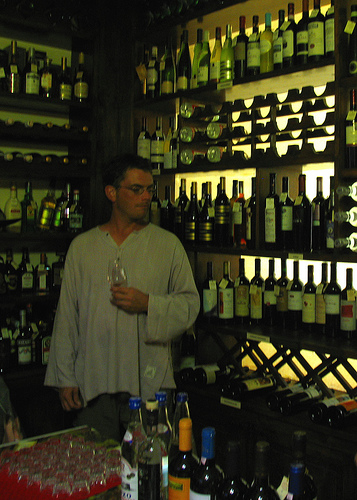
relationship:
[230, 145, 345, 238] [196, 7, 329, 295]
bottles on shelves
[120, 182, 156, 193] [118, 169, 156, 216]
glasses are on face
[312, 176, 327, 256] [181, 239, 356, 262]
bottle on top of shelf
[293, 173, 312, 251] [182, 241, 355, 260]
wine bottle on shelf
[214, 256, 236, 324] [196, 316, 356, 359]
bottle on top of shelf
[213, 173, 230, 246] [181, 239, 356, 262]
wine bottle on top of shelf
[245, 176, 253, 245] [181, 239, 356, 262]
wine bottle on top of shelf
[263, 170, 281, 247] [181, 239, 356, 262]
wine bottle on top of shelf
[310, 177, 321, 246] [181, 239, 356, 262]
wine bottle on top of shelf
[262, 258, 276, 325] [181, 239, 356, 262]
wine bottle on top of shelf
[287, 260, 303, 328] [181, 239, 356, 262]
wine bottle on top of shelf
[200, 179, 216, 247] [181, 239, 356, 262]
bottle on top of shelf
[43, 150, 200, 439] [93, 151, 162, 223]
man has head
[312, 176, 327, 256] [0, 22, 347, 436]
bottle on shelf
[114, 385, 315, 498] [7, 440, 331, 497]
bottle on table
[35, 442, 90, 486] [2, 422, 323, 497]
glasses on table